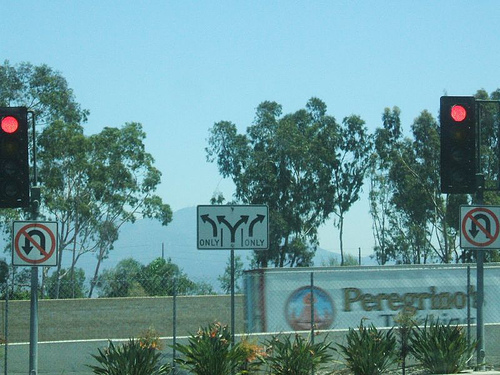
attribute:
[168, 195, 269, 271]
turn — sign, metal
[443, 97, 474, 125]
light — red, redy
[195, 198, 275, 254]
sign — arrow, street, turn, black, road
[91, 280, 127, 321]
fence — chain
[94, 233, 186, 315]
wall — concrete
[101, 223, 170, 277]
plant — green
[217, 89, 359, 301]
tree — green, trunk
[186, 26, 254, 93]
sky — blue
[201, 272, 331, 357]
barrier — concrete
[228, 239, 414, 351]
truck — white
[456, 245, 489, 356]
pole — metal